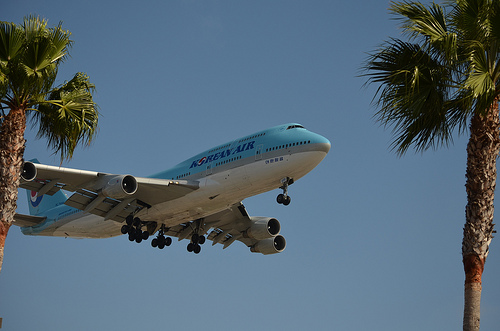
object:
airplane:
[3, 115, 345, 259]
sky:
[4, 4, 500, 330]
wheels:
[272, 192, 296, 207]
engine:
[98, 171, 147, 200]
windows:
[204, 159, 216, 178]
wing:
[7, 154, 209, 225]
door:
[251, 142, 266, 161]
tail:
[0, 156, 51, 203]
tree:
[0, 4, 102, 272]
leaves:
[22, 32, 45, 57]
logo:
[186, 137, 259, 170]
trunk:
[0, 105, 31, 244]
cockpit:
[278, 118, 313, 134]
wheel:
[184, 241, 203, 256]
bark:
[9, 134, 18, 151]